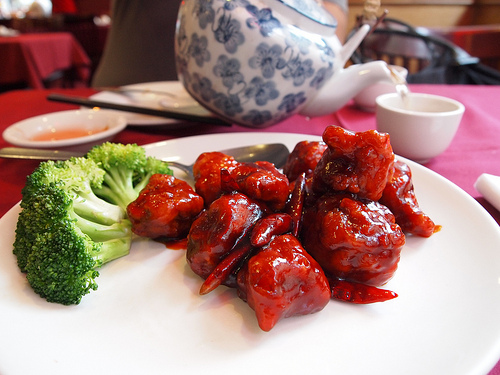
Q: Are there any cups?
A: Yes, there is a cup.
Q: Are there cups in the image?
A: Yes, there is a cup.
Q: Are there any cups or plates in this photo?
A: Yes, there is a cup.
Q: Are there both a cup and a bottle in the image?
A: No, there is a cup but no bottles.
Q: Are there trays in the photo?
A: No, there are no trays.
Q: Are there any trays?
A: No, there are no trays.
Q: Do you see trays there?
A: No, there are no trays.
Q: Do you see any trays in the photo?
A: No, there are no trays.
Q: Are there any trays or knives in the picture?
A: No, there are no trays or knives.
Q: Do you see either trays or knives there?
A: No, there are no trays or knives.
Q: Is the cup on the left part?
A: No, the cup is on the right of the image.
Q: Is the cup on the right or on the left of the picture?
A: The cup is on the right of the image.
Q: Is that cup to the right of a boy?
A: No, the cup is to the right of the spoon.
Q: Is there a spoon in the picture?
A: Yes, there is a spoon.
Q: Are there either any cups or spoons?
A: Yes, there is a spoon.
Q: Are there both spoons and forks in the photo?
A: No, there is a spoon but no forks.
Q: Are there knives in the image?
A: No, there are no knives.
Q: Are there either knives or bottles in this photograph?
A: No, there are no knives or bottles.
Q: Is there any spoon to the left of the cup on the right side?
A: Yes, there is a spoon to the left of the cup.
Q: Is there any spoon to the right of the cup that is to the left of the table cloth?
A: No, the spoon is to the left of the cup.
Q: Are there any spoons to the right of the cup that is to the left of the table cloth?
A: No, the spoon is to the left of the cup.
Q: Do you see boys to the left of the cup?
A: No, there is a spoon to the left of the cup.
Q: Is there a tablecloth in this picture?
A: Yes, there is a tablecloth.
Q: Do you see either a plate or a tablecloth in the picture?
A: Yes, there is a tablecloth.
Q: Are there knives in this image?
A: No, there are no knives.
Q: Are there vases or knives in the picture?
A: No, there are no knives or vases.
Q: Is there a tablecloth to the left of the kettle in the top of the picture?
A: Yes, there is a tablecloth to the left of the kettle.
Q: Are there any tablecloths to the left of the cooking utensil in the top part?
A: Yes, there is a tablecloth to the left of the kettle.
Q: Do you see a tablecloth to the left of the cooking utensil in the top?
A: Yes, there is a tablecloth to the left of the kettle.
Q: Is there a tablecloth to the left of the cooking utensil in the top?
A: Yes, there is a tablecloth to the left of the kettle.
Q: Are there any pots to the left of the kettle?
A: No, there is a tablecloth to the left of the kettle.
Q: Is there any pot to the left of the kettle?
A: No, there is a tablecloth to the left of the kettle.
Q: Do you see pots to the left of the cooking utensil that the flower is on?
A: No, there is a tablecloth to the left of the kettle.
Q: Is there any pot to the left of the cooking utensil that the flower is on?
A: No, there is a tablecloth to the left of the kettle.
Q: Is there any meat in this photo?
A: Yes, there is meat.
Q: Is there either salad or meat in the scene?
A: Yes, there is meat.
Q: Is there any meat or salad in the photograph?
A: Yes, there is meat.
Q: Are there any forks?
A: No, there are no forks.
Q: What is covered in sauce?
A: The meat is covered in sauce.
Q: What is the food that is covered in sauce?
A: The food is meat.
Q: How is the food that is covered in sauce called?
A: The food is meat.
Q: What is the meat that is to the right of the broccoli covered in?
A: The meat is covered in sauce.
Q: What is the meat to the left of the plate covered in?
A: The meat is covered in sauce.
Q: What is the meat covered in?
A: The meat is covered in sauce.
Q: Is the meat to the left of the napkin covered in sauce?
A: Yes, the meat is covered in sauce.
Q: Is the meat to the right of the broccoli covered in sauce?
A: Yes, the meat is covered in sauce.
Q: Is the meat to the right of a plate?
A: No, the meat is to the left of a plate.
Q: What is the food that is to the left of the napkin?
A: The food is meat.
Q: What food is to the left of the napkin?
A: The food is meat.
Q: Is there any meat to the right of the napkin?
A: No, the meat is to the left of the napkin.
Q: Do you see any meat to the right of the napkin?
A: No, the meat is to the left of the napkin.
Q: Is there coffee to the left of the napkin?
A: No, there is meat to the left of the napkin.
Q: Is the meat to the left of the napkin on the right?
A: Yes, the meat is to the left of the napkin.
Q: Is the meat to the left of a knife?
A: No, the meat is to the left of the napkin.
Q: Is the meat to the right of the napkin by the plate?
A: No, the meat is to the left of the napkin.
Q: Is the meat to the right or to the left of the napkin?
A: The meat is to the left of the napkin.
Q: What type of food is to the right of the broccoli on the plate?
A: The food is meat.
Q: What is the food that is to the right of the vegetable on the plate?
A: The food is meat.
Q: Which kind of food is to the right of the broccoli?
A: The food is meat.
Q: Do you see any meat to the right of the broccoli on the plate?
A: Yes, there is meat to the right of the broccoli.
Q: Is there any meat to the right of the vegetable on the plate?
A: Yes, there is meat to the right of the broccoli.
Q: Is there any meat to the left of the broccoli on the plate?
A: No, the meat is to the right of the broccoli.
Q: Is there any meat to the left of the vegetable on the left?
A: No, the meat is to the right of the broccoli.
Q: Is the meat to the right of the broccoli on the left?
A: Yes, the meat is to the right of the broccoli.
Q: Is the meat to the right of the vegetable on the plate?
A: Yes, the meat is to the right of the broccoli.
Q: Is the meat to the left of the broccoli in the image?
A: No, the meat is to the right of the broccoli.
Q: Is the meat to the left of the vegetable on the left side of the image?
A: No, the meat is to the right of the broccoli.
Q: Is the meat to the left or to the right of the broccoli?
A: The meat is to the right of the broccoli.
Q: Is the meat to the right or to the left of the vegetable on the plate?
A: The meat is to the right of the broccoli.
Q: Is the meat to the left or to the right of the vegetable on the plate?
A: The meat is to the right of the broccoli.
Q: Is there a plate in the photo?
A: Yes, there is a plate.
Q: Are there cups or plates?
A: Yes, there is a plate.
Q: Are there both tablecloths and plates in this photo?
A: Yes, there are both a plate and a tablecloth.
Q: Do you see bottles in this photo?
A: No, there are no bottles.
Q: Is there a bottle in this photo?
A: No, there are no bottles.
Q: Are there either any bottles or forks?
A: No, there are no bottles or forks.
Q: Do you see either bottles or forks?
A: No, there are no bottles or forks.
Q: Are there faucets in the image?
A: No, there are no faucets.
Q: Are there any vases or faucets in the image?
A: No, there are no faucets or vases.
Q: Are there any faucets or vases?
A: No, there are no faucets or vases.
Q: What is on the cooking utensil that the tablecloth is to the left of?
A: The flower is on the kettle.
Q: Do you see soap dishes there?
A: No, there are no soap dishes.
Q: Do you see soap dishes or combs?
A: No, there are no soap dishes or combs.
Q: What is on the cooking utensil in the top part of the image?
A: The flower is on the kettle.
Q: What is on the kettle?
A: The flower is on the kettle.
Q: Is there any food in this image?
A: Yes, there is food.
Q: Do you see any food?
A: Yes, there is food.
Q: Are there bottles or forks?
A: No, there are no forks or bottles.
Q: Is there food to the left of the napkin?
A: Yes, there is food to the left of the napkin.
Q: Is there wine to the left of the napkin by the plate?
A: No, there is food to the left of the napkin.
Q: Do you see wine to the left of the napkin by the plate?
A: No, there is food to the left of the napkin.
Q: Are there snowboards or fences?
A: No, there are no fences or snowboards.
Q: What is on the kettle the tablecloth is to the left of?
A: The flower is on the kettle.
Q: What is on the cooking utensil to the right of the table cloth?
A: The flower is on the kettle.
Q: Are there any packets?
A: No, there are no packets.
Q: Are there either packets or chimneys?
A: No, there are no packets or chimneys.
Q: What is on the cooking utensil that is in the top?
A: The flower is on the kettle.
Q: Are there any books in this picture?
A: No, there are no books.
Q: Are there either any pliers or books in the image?
A: No, there are no books or pliers.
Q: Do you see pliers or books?
A: No, there are no books or pliers.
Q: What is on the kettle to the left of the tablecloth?
A: The flower is on the kettle.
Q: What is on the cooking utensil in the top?
A: The flower is on the kettle.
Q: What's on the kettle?
A: The flower is on the kettle.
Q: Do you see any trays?
A: No, there are no trays.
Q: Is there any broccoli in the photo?
A: Yes, there is broccoli.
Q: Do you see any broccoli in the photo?
A: Yes, there is broccoli.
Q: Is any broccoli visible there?
A: Yes, there is broccoli.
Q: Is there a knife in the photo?
A: No, there are no knives.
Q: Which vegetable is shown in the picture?
A: The vegetable is broccoli.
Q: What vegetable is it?
A: The vegetable is broccoli.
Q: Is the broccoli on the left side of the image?
A: Yes, the broccoli is on the left of the image.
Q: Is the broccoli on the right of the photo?
A: No, the broccoli is on the left of the image.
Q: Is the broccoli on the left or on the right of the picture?
A: The broccoli is on the left of the image.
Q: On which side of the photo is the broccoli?
A: The broccoli is on the left of the image.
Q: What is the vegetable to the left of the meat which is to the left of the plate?
A: The vegetable is broccoli.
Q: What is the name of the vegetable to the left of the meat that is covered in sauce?
A: The vegetable is broccoli.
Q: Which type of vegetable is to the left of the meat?
A: The vegetable is broccoli.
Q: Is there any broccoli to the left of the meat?
A: Yes, there is broccoli to the left of the meat.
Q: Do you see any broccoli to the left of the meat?
A: Yes, there is broccoli to the left of the meat.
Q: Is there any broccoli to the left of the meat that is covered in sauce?
A: Yes, there is broccoli to the left of the meat.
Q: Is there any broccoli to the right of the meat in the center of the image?
A: No, the broccoli is to the left of the meat.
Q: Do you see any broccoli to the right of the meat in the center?
A: No, the broccoli is to the left of the meat.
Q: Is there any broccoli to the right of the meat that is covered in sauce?
A: No, the broccoli is to the left of the meat.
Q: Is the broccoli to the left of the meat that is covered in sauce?
A: Yes, the broccoli is to the left of the meat.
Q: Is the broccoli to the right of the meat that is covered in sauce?
A: No, the broccoli is to the left of the meat.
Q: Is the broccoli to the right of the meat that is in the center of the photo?
A: No, the broccoli is to the left of the meat.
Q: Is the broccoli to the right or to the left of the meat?
A: The broccoli is to the left of the meat.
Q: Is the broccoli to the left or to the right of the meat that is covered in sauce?
A: The broccoli is to the left of the meat.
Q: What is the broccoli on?
A: The broccoli is on the plate.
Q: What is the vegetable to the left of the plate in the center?
A: The vegetable is broccoli.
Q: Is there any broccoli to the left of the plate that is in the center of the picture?
A: Yes, there is broccoli to the left of the plate.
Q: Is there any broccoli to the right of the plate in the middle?
A: No, the broccoli is to the left of the plate.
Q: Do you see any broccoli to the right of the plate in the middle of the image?
A: No, the broccoli is to the left of the plate.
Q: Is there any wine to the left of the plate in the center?
A: No, there is broccoli to the left of the plate.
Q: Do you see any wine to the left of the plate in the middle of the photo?
A: No, there is broccoli to the left of the plate.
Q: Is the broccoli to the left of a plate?
A: Yes, the broccoli is to the left of a plate.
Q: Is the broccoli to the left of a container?
A: No, the broccoli is to the left of a plate.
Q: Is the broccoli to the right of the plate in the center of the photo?
A: No, the broccoli is to the left of the plate.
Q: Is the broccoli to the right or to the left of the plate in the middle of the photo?
A: The broccoli is to the left of the plate.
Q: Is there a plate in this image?
A: Yes, there is a plate.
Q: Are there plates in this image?
A: Yes, there is a plate.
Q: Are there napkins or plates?
A: Yes, there is a plate.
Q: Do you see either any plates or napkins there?
A: Yes, there is a plate.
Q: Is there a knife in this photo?
A: No, there are no knives.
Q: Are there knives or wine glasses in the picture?
A: No, there are no knives or wine glasses.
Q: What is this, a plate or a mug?
A: This is a plate.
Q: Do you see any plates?
A: Yes, there is a plate.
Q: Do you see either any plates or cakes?
A: Yes, there is a plate.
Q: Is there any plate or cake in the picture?
A: Yes, there is a plate.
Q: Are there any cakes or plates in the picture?
A: Yes, there is a plate.